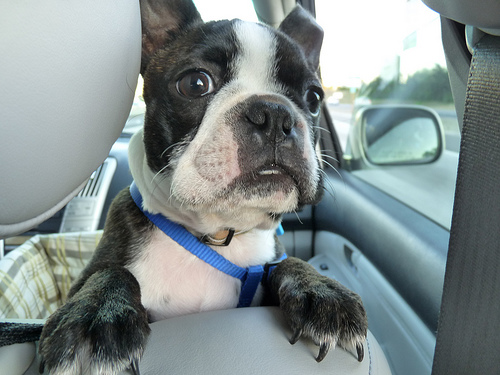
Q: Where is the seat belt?
A: On the side.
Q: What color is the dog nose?
A: All black.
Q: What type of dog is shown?
A: Boston terrier.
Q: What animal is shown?
A: Dog.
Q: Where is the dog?
A: Car.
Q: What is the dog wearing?
A: Collar.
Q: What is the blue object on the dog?
A: Harness.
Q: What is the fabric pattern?
A: Plaid.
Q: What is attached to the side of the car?
A: Mirror.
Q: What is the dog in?
A: Basket.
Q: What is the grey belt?
A: Seatbelt.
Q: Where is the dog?
A: In car.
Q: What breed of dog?
A: Boston terrier.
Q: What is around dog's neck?
A: Collar.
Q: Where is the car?
A: On highway.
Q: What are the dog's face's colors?
A: Black and white.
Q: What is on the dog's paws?
A: Claws.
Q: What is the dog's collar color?
A: Blue.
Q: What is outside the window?
A: Sideview mirror.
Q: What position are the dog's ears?
A: Up.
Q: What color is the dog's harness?
A: Blue.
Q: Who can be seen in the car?
A: A dog.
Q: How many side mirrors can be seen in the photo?
A: One.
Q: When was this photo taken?
A: Daytime.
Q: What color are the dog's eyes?
A: Brown.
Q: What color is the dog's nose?
A: Black.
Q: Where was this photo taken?
A: Inside a vehicle.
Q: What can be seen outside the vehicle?
A: A road.